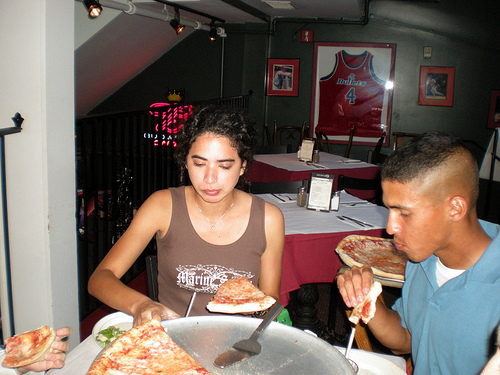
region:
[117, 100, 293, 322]
Woman wearing a brown tank top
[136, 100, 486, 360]
The people are eating pizza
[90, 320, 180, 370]
A slice of pizza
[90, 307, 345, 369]
The platter is round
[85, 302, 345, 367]
The platter is silver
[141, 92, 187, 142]
Red sign behind woman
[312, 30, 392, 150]
Red jersey framed on wall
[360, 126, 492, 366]
Man wearing a blue shirt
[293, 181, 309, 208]
Brown and silver shaker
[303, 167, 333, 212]
White sign on table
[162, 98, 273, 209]
This girl looks hungry.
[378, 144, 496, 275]
This man is eating food.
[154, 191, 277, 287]
The girls tank top is brown.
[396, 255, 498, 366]
The mans shirt is blue.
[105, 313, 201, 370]
This is cheese pizza.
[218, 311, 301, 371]
This is used to serve pizza.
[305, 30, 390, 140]
The jersey is in a frame.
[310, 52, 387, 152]
This jersey is red and blue.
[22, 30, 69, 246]
The wall is white in color.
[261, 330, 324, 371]
The pizza platter is silver.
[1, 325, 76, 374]
a hand holding a piece of pizza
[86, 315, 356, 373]
a pizza on a large silver tray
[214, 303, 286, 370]
a silver pizza server resting on silver tray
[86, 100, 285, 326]
a woman wearing a brown tank top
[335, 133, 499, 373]
a man wearing a light blue shirt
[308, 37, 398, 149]
a framed red jersey with the number four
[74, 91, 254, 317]
black wrought iron railing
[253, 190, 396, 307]
a red table cloth with white on top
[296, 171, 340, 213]
a napkin holder and salt and pepper shakers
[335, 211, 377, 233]
a knife nad fork on a white napkin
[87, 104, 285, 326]
Woman sitting by a table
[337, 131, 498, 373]
Man sitting by the table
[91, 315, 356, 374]
Pizza tray on the table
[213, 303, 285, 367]
Pizza server on the tray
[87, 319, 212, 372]
Pizza on the pizza tray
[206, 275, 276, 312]
A piece of pizza in the woman's hand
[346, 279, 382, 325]
Part of a piece of pizza in the man's hand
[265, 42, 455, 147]
Pictures on the wall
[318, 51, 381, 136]
Red shirt on the big piture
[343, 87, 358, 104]
Number on the red shirt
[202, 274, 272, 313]
a slice of pizza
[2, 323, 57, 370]
a slice of pizza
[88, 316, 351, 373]
a metal pizza tray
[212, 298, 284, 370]
a metal serving utensil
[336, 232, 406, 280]
a whole pizza pie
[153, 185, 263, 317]
a brown printed tank top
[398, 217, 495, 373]
a light blue polo shirt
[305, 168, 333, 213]
a chrome napkin holder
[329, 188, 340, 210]
a glass salt shaker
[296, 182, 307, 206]
a glass pepper shaker